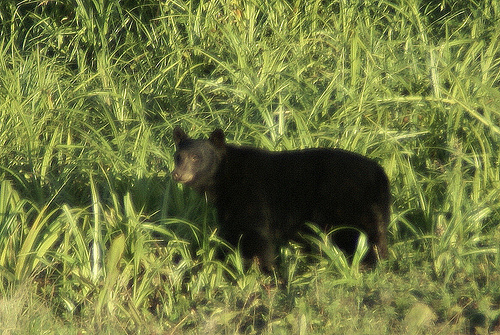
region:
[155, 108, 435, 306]
This is a wild animal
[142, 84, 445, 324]
This is a black wild animal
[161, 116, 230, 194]
Head of a wild animal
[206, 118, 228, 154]
Ear of a wild animal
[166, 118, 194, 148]
Ear of a wild animal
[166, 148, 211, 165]
Eyes of a wild animal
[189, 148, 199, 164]
Eye of a wild animal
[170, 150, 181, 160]
Eye of a wild animal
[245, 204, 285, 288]
Leg of a wild animal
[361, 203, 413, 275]
Leg of a wild animal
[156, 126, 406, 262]
this is a wolf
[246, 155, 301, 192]
the wolf is black in color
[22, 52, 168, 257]
this is a grass area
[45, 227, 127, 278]
the grass is green in color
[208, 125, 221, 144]
this is the left ear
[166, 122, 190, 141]
this is the right ear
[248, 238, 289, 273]
this is the front leg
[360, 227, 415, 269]
this is the hind leg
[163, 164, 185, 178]
this is the nose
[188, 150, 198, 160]
this is the eye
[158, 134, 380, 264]
bear is black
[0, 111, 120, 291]
weeds are high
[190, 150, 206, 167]
bear's eye is black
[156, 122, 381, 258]
bear looking to his right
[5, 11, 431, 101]
grass is tall and green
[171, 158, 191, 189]
part of bear face is light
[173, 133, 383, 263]
bear is a cub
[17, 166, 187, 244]
shadows in the grass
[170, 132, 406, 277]
bear is in the grass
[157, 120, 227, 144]
bear's ears are brown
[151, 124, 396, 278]
black bear in grass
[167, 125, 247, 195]
head of black bear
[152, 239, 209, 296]
patch of green grass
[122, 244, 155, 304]
patch of green grass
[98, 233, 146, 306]
patch of green grass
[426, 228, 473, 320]
patch of green grass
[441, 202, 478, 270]
patch of green grass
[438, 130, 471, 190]
patch of green grass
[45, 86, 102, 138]
patch of green grass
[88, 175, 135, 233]
patch of green grass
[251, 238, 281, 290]
leg of black bear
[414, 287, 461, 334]
patch of green grass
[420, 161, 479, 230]
patch of green grass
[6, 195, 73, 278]
patch of green grass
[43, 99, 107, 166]
patch of green grass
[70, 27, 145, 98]
patch of green grass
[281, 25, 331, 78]
patch of green grass